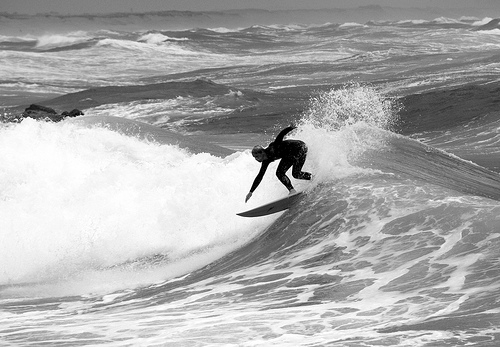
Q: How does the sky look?
A: Cloudy.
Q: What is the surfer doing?
A: Riding a wave.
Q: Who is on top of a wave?
A: Surfer.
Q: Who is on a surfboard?
A: Surfer.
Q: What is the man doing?
A: Surfing.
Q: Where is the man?
A: On a surfboard.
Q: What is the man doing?
A: Riding a large wave.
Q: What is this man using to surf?
A: A surf board.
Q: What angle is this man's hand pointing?
A: Down.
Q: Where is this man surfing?
A: In the ocean.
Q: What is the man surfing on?
A: Wave.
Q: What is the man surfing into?
A: A Wave.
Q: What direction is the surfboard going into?
A: Down.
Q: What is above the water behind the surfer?
A: Splashing waves.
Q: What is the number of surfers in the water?
A: One.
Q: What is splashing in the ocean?
A: A Wave.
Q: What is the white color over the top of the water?
A: Foam.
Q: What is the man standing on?
A: A surfboard.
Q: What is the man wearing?
A: A wetsuit.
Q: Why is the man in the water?
A: He is surfing.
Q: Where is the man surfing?
A: In the ocean.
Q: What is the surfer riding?
A: Wave.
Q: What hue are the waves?
A: Gray.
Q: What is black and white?
A: Picture.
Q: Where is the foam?
A: Ocean.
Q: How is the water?
A: Gray.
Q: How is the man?
A: Wet.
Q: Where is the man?
A: On surfboard.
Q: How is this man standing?
A: With balance on a surfboard.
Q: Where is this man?
A: Beach.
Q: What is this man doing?
A: Surfing.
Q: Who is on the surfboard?
A: A man.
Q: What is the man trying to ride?
A: A wave.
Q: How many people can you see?
A: 1.